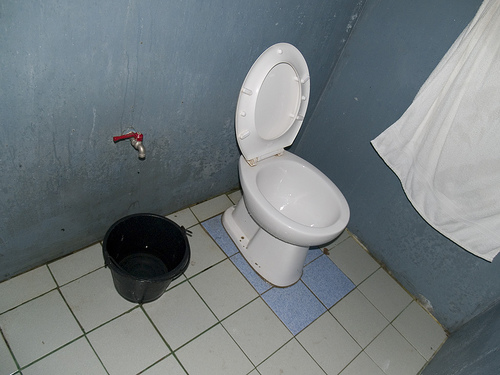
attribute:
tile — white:
[0, 264, 57, 312]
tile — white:
[3, 285, 93, 368]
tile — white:
[18, 332, 108, 371]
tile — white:
[81, 301, 171, 371]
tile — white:
[57, 264, 139, 333]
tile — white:
[140, 277, 216, 353]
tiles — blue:
[192, 196, 369, 343]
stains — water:
[24, 107, 116, 198]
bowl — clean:
[214, 35, 355, 289]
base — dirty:
[217, 191, 314, 301]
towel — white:
[365, 0, 498, 269]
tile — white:
[184, 254, 263, 324]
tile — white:
[216, 292, 297, 367]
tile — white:
[296, 314, 363, 374]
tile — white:
[395, 294, 456, 368]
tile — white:
[295, 306, 364, 371]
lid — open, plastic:
[228, 40, 314, 169]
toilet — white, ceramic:
[215, 36, 353, 291]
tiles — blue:
[198, 194, 375, 335]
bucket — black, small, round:
[95, 207, 198, 311]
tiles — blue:
[201, 199, 366, 339]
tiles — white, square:
[6, 171, 450, 373]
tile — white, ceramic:
[5, 177, 452, 371]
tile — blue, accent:
[192, 186, 369, 344]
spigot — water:
[109, 125, 154, 165]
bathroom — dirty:
[5, 1, 494, 373]